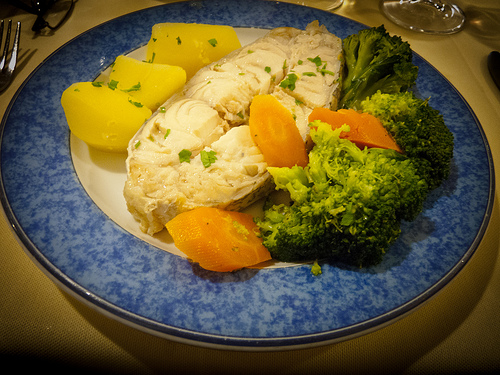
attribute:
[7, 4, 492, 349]
plate — blue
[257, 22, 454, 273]
broccoli — green, cooked, steamed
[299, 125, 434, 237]
broccoli — green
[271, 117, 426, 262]
broccoli — green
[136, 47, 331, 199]
fish — big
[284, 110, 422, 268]
broccoli — green 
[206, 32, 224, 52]
parsley flake — green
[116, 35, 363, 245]
fish — poached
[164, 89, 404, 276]
carrots — cooked, sliced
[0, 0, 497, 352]
blue plate — round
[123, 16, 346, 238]
fish — white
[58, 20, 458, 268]
plate — filled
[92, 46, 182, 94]
potatoes — white, boiled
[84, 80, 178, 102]
parsley — green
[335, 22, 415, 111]
spear — broccoli 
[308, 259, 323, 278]
crumb — tiny 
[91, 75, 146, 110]
herbs — green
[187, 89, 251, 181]
white fish — large, cooked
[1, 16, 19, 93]
fork — silver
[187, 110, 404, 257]
carrots — sliced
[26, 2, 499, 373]
plate — beautiful blue 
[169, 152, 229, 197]
chives — green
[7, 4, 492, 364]
placement — yellow